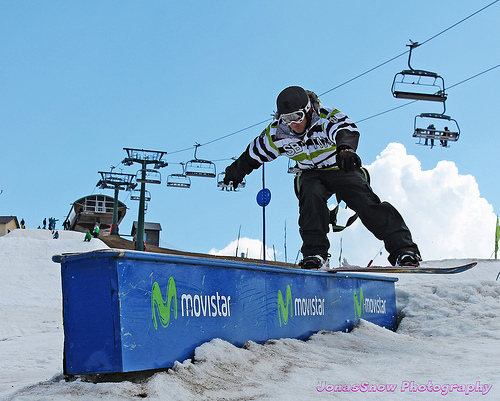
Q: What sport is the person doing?
A: Snowboarding.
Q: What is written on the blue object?
A: Movistar.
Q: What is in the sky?
A: Clouds.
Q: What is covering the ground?
A: Snow.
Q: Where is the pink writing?
A: Bottom right side of the image.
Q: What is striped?
A: Ski jacket.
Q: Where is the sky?
A: Top of the photo.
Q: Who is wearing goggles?
A: Snowboarder.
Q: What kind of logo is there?
A: Movistar.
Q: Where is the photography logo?
A: Bottom right corner.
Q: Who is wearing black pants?
A: Snowboarder.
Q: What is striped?
A: Ski jacket.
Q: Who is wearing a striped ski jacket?
A: Snowboarder.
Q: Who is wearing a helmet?
A: Snowboarder.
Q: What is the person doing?
A: Snowboarding.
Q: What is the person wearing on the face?
A: Goggles.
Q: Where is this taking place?
A: Snow covered mountains.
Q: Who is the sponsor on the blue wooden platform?
A: Movistar.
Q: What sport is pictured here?
A: Snowboarding.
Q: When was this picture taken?
A: Daytime.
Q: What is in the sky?
A: A skilift.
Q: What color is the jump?
A: Blue.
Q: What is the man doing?
A: A snowboarding trick.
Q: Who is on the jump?
A: A snowboarder.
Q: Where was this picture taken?
A: A ski slope.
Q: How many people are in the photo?
A: One.